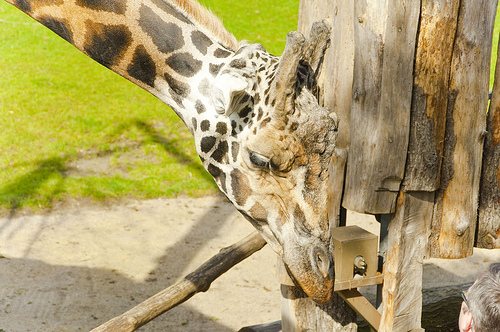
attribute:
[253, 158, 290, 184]
eye — dark, brown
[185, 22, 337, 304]
giraffe — here, eating, watching, brown, bending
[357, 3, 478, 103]
bar — wooden, metal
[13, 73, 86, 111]
grass — here, field, green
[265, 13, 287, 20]
ground — bare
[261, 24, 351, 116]
ears — white, brown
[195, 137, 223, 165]
spots — brown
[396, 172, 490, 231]
fence — wooden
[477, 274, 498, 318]
hair — brown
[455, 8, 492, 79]
platform — wooden, wood